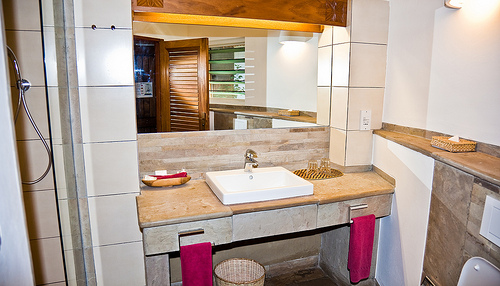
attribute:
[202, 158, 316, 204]
bathroom sink — white, large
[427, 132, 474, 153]
basket — wooden, straw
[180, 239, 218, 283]
towel — pink, long, red, hanging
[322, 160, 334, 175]
cup — clear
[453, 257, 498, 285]
toilet seat — white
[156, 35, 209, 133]
door — wooden, brown, wood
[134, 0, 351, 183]
bathroom mirror — large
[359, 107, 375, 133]
wall switch — white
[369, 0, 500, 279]
wall — painted, white, tiled, here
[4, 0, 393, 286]
wall — tiled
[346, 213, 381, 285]
towel — violet, hanging, pink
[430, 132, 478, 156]
napkin holder — here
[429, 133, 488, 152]
tissue dispenser — here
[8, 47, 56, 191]
shower hose — here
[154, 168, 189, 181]
washcloth — here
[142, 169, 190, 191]
soap cotainer — here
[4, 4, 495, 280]
bathroom — tidy, neat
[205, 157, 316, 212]
sink — white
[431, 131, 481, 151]
tissue box — here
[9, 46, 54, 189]
shower cord — here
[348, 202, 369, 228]
towel holder — here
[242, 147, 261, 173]
faucet — silver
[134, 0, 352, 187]
mirror — large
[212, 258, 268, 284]
trash can — round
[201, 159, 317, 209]
basin — white